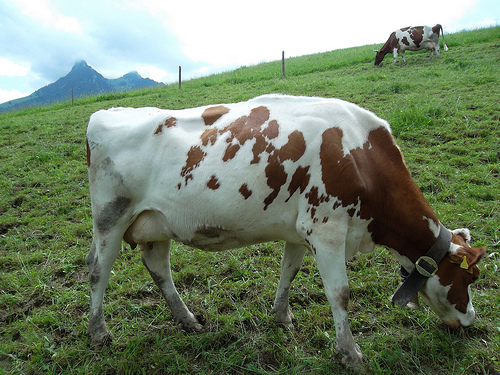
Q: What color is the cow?
A: White and brown.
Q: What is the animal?
A: A cow.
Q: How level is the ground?
A: Sloped.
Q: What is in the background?
A: Mountains.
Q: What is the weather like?
A: Cloudy.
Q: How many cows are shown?
A: Two.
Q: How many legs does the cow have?
A: Four.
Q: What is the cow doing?
A: Grazing.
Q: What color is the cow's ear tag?
A: Yellow.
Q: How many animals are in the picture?
A: 2.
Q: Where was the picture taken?
A: Cow pasture.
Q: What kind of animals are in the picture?
A: Cows.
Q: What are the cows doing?
A: Grazing.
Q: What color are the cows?
A: Brown and white.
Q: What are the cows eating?
A: Grass.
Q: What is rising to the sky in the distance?
A: A mountain.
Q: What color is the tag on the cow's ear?
A: Yellow.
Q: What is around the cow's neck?
A: A bell collar.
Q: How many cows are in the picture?
A: Two.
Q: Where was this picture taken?
A: In a cow field.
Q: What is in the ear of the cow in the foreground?
A: A tag.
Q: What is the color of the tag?
A: Yellow.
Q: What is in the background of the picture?
A: A mountain.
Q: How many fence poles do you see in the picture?
A: Three.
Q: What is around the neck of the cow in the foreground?
A: A collar.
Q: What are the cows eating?
A: Grass.